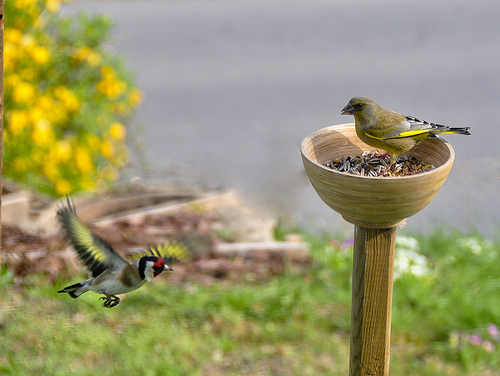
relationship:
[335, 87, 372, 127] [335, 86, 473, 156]
head of bird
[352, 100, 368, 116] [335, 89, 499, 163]
eye of bird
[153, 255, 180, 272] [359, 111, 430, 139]
beak of bird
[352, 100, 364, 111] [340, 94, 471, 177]
eye of bird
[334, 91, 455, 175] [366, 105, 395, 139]
bird with feathers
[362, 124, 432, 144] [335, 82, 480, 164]
wing of a bird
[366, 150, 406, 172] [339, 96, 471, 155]
legs of a bird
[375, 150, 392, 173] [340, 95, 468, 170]
feet of a bird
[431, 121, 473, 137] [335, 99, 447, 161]
tail of a bird